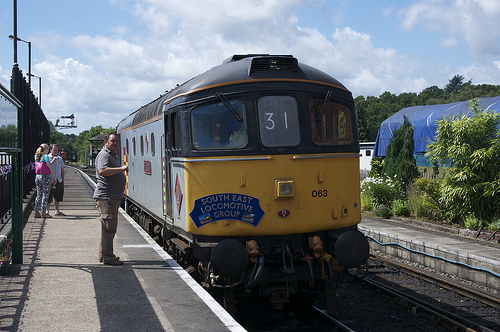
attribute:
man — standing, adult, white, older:
[94, 130, 136, 264]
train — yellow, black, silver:
[113, 51, 368, 292]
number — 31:
[257, 103, 295, 135]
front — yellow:
[184, 93, 362, 238]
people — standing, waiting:
[30, 142, 72, 218]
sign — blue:
[190, 193, 267, 226]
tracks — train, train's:
[247, 253, 492, 327]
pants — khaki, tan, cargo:
[95, 199, 124, 262]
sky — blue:
[5, 3, 498, 141]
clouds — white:
[40, 5, 463, 122]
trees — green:
[1, 75, 499, 231]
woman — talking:
[34, 142, 54, 221]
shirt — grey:
[91, 147, 130, 200]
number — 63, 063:
[312, 185, 330, 199]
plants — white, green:
[363, 95, 499, 225]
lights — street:
[6, 35, 48, 131]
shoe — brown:
[107, 259, 124, 266]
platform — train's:
[7, 160, 237, 331]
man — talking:
[45, 141, 70, 217]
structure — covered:
[367, 96, 500, 174]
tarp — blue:
[372, 96, 499, 161]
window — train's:
[258, 96, 300, 147]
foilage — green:
[0, 75, 499, 162]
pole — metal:
[26, 42, 35, 92]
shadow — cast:
[15, 253, 162, 331]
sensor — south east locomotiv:
[276, 206, 292, 218]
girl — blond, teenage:
[33, 142, 60, 218]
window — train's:
[308, 97, 355, 147]